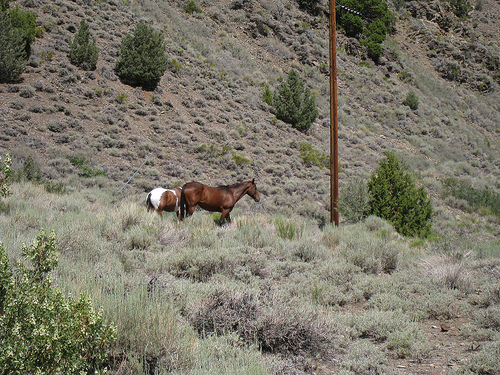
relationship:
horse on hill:
[180, 178, 262, 224] [2, 177, 500, 374]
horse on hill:
[143, 186, 183, 221] [2, 177, 500, 374]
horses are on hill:
[180, 178, 262, 224] [2, 177, 500, 374]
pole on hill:
[326, 0, 345, 228] [2, 177, 500, 374]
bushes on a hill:
[1, 2, 319, 139] [0, 1, 499, 219]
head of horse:
[242, 177, 262, 203] [180, 178, 262, 224]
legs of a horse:
[186, 206, 232, 227] [180, 178, 262, 224]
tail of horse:
[179, 183, 188, 221] [180, 178, 262, 224]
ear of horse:
[249, 178, 257, 185] [180, 178, 262, 224]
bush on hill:
[113, 19, 170, 92] [0, 1, 499, 219]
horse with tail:
[180, 178, 262, 224] [179, 183, 188, 221]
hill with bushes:
[0, 1, 499, 219] [1, 2, 319, 139]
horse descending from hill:
[180, 178, 262, 224] [2, 177, 500, 374]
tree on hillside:
[365, 154, 435, 244] [0, 1, 499, 219]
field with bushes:
[0, 1, 499, 219] [1, 2, 319, 139]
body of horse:
[179, 180, 241, 210] [180, 178, 262, 224]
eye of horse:
[251, 185, 258, 191] [180, 178, 262, 224]